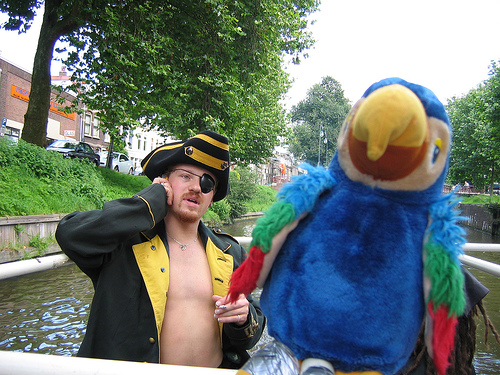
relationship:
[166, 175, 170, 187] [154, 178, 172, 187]
ring on finger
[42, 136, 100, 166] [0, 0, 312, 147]
car next to tree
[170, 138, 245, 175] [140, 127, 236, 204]
buttons on hat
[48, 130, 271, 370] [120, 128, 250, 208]
man wearing hat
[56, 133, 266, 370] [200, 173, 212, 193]
man wearing eye patch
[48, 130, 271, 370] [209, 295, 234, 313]
man holding cigarette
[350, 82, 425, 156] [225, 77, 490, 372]
nose on parrot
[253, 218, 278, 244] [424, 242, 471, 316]
green on arm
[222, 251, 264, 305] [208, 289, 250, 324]
red on hand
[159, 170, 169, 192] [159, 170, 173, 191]
phone on ear